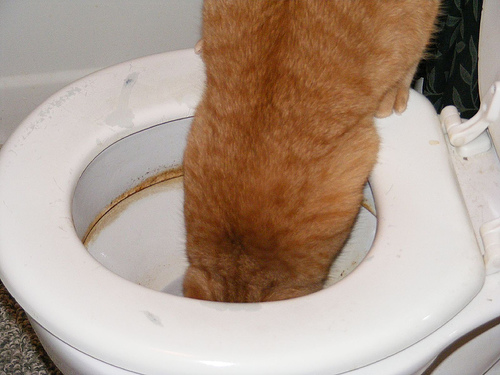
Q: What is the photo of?
A: A cat.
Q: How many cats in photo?
A: One.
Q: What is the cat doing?
A: Sticking head in toilet.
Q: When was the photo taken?
A: Daytime.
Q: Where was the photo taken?
A: In a bathroom.